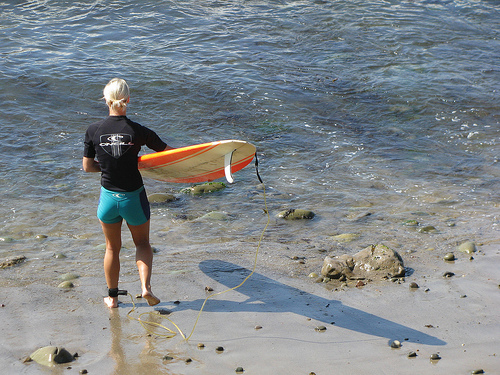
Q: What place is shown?
A: It is a beach.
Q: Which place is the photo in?
A: It is at the beach.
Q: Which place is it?
A: It is a beach.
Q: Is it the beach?
A: Yes, it is the beach.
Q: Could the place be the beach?
A: Yes, it is the beach.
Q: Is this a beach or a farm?
A: It is a beach.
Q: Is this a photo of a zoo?
A: No, the picture is showing a beach.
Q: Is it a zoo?
A: No, it is a beach.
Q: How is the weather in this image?
A: It is sunny.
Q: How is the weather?
A: It is sunny.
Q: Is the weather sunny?
A: Yes, it is sunny.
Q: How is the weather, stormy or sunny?
A: It is sunny.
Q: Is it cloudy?
A: No, it is sunny.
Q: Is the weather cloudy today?
A: No, it is sunny.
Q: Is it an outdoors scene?
A: Yes, it is outdoors.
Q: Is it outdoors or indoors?
A: It is outdoors.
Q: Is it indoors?
A: No, it is outdoors.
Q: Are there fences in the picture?
A: No, there are no fences.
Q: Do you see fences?
A: No, there are no fences.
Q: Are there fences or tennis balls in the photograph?
A: No, there are no fences or tennis balls.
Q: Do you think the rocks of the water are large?
A: Yes, the rocks are large.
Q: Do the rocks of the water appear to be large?
A: Yes, the rocks are large.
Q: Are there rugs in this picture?
A: No, there are no rugs.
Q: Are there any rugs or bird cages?
A: No, there are no rugs or bird cages.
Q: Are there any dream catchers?
A: No, there are no dream catchers.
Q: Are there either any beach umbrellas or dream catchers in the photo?
A: No, there are no dream catchers or beach umbrellas.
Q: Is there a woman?
A: Yes, there is a woman.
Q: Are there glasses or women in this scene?
A: Yes, there is a woman.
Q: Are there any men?
A: No, there are no men.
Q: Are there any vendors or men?
A: No, there are no men or vendors.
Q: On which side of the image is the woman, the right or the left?
A: The woman is on the left of the image.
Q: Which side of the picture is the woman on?
A: The woman is on the left of the image.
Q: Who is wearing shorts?
A: The woman is wearing shorts.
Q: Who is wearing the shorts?
A: The woman is wearing shorts.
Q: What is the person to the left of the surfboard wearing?
A: The woman is wearing shorts.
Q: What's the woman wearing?
A: The woman is wearing shorts.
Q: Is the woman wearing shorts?
A: Yes, the woman is wearing shorts.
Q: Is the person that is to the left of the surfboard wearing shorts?
A: Yes, the woman is wearing shorts.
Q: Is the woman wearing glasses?
A: No, the woman is wearing shorts.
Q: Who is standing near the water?
A: The woman is standing near the water.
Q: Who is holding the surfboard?
A: The woman is holding the surfboard.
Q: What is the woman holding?
A: The woman is holding the surfboard.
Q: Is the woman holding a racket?
A: No, the woman is holding a surfboard.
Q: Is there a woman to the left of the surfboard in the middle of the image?
A: Yes, there is a woman to the left of the surfboard.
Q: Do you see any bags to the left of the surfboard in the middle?
A: No, there is a woman to the left of the surfboard.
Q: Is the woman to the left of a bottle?
A: No, the woman is to the left of the surfboard.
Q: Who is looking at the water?
A: The woman is looking at the water.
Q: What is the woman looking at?
A: The woman is looking at the water.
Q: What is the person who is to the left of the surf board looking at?
A: The woman is looking at the water.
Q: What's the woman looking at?
A: The woman is looking at the water.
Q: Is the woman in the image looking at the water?
A: Yes, the woman is looking at the water.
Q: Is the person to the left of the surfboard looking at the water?
A: Yes, the woman is looking at the water.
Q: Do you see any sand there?
A: Yes, there is sand.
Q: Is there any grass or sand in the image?
A: Yes, there is sand.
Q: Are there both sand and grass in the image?
A: No, there is sand but no grass.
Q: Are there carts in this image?
A: No, there are no carts.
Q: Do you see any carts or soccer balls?
A: No, there are no carts or soccer balls.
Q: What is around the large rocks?
A: The sand is around the rocks.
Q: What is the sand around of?
A: The sand is around the rocks.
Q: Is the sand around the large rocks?
A: Yes, the sand is around the rocks.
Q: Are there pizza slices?
A: No, there are no pizza slices.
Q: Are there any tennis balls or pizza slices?
A: No, there are no pizza slices or tennis balls.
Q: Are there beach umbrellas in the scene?
A: No, there are no beach umbrellas.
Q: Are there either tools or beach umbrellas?
A: No, there are no beach umbrellas or tools.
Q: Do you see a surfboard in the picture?
A: Yes, there is a surfboard.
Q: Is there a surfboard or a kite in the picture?
A: Yes, there is a surfboard.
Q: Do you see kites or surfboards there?
A: Yes, there is a surfboard.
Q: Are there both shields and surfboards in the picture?
A: No, there is a surfboard but no shields.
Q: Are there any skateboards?
A: No, there are no skateboards.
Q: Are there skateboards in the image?
A: No, there are no skateboards.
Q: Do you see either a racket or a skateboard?
A: No, there are no skateboards or rackets.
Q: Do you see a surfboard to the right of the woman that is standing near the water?
A: Yes, there is a surfboard to the right of the woman.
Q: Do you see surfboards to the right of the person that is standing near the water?
A: Yes, there is a surfboard to the right of the woman.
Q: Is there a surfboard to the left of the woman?
A: No, the surfboard is to the right of the woman.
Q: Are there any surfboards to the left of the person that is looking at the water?
A: No, the surfboard is to the right of the woman.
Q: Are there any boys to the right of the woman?
A: No, there is a surfboard to the right of the woman.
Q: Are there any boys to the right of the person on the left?
A: No, there is a surfboard to the right of the woman.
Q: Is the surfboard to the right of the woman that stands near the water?
A: Yes, the surfboard is to the right of the woman.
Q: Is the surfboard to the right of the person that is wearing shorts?
A: Yes, the surfboard is to the right of the woman.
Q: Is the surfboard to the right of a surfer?
A: No, the surfboard is to the right of the woman.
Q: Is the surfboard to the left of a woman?
A: No, the surfboard is to the right of a woman.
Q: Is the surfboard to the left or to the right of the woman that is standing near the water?
A: The surfboard is to the right of the woman.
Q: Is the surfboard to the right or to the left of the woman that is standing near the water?
A: The surfboard is to the right of the woman.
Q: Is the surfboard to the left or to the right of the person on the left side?
A: The surfboard is to the right of the woman.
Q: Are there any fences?
A: No, there are no fences.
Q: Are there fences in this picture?
A: No, there are no fences.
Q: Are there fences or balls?
A: No, there are no fences or balls.